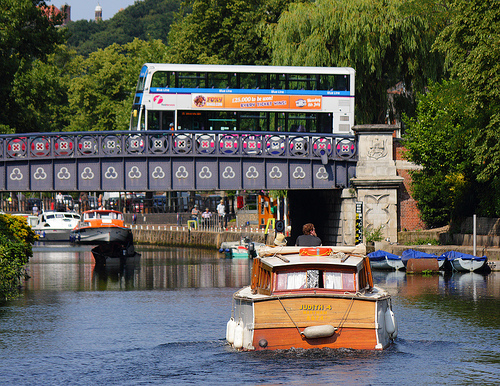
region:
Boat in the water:
[221, 222, 421, 363]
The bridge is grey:
[6, 121, 355, 208]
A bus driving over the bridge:
[13, 42, 364, 193]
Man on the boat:
[285, 219, 326, 254]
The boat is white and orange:
[73, 207, 157, 252]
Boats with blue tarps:
[361, 231, 484, 273]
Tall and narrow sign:
[350, 197, 370, 259]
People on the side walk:
[183, 190, 240, 236]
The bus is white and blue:
[125, 57, 365, 148]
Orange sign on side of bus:
[188, 88, 330, 112]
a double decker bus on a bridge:
[127, 53, 359, 147]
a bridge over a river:
[0, 120, 358, 202]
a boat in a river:
[219, 220, 409, 363]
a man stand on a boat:
[286, 220, 326, 254]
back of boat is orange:
[241, 291, 383, 359]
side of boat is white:
[223, 288, 258, 350]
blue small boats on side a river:
[368, 242, 484, 279]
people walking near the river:
[181, 195, 232, 231]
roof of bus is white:
[126, 53, 362, 134]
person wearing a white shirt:
[211, 195, 234, 229]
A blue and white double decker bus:
[131, 61, 355, 157]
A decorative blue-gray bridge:
[1, 129, 404, 252]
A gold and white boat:
[222, 246, 397, 351]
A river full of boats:
[2, 209, 497, 382]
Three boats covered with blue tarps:
[368, 244, 487, 277]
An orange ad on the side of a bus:
[190, 92, 322, 109]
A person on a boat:
[292, 224, 322, 246]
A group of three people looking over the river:
[190, 199, 229, 229]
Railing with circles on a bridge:
[1, 133, 357, 163]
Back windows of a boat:
[272, 262, 361, 294]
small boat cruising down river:
[223, 243, 405, 364]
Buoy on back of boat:
[281, 308, 349, 350]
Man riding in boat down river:
[286, 211, 323, 263]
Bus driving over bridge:
[1, 51, 402, 220]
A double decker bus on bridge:
[119, 53, 361, 143]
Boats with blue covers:
[369, 247, 496, 275]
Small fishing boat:
[78, 239, 152, 271]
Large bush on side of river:
[5, 212, 39, 294]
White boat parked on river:
[31, 200, 73, 254]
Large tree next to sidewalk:
[396, 67, 497, 254]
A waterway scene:
[4, 2, 496, 376]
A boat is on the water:
[222, 222, 402, 359]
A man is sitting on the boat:
[294, 214, 326, 252]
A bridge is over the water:
[0, 121, 405, 224]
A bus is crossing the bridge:
[129, 57, 357, 159]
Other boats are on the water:
[24, 205, 144, 265]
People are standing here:
[189, 197, 230, 236]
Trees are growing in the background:
[2, 1, 409, 130]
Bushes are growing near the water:
[0, 210, 40, 301]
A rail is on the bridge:
[0, 130, 355, 161]